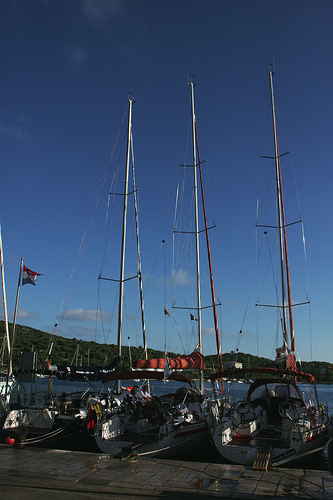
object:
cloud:
[55, 0, 135, 73]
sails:
[218, 79, 310, 408]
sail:
[218, 368, 305, 388]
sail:
[111, 369, 202, 387]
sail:
[20, 372, 89, 385]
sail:
[132, 346, 206, 375]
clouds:
[3, 1, 252, 347]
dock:
[2, 444, 332, 499]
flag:
[19, 263, 41, 290]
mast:
[112, 89, 133, 393]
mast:
[184, 73, 207, 392]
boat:
[208, 112, 330, 471]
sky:
[1, 2, 332, 318]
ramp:
[117, 434, 153, 460]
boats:
[0, 225, 110, 453]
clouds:
[0, 0, 332, 365]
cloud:
[0, 16, 326, 365]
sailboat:
[212, 69, 330, 462]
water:
[7, 375, 330, 411]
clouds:
[61, 300, 110, 328]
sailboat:
[88, 70, 228, 461]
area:
[4, 10, 331, 367]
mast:
[265, 65, 291, 410]